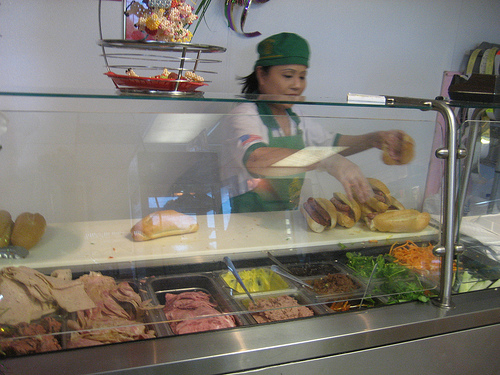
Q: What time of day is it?
A: Day time.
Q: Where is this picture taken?
A: Restaurant.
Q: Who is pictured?
A: Woman.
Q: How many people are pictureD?
A: One.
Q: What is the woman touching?
A: Sandwich.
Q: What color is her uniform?
A: Green.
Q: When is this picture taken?
A: During lunch.